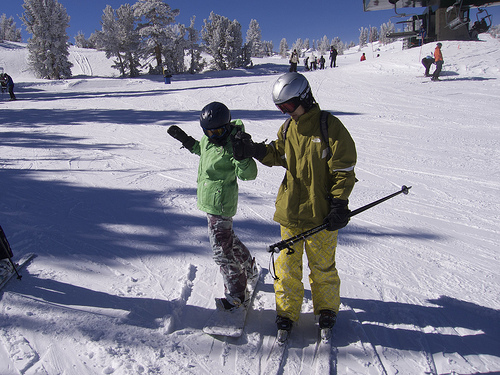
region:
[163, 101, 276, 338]
child balancing on top of a snow board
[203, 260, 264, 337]
snow board underneath child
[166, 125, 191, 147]
black mitten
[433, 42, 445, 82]
person wearing an orange jacket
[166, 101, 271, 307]
child weaqring a green jacket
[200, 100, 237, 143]
child wearing a black helmet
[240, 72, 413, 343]
person holding ski poles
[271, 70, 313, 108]
silver helmet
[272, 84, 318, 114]
ski goggles on top of helmet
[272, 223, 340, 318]
yellow ski pants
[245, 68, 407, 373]
a snow skier on slope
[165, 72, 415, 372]
a snow skier helping a snowboarder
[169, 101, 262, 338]
a snow boarder on slope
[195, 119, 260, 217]
a light green winter coat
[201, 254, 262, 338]
a snow covered snowboard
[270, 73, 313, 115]
a silver protective helmet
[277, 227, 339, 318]
a yellow pair of snow pants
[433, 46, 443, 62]
an orange winter coat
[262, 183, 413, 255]
a black snow pole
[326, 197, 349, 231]
a black winter snow glove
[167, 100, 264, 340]
boy standing on skateboard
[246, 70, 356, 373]
person wearing skis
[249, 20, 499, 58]
trees in the distance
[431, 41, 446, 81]
person standing on the snow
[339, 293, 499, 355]
peoples shadow on the snow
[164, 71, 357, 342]
two people wearing helmet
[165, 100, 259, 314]
person wearing green helmet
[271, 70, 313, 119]
grey helmet on head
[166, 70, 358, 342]
two people wearing gloves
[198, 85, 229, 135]
Person wearing black helmet.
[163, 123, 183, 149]
Person wearing black glove.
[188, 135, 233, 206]
Person wearing green jacket.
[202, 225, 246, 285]
Person wearing gray pants.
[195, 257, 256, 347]
Person standing on snowboard.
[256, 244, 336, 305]
Person wearing yellow pants.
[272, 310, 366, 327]
Person wearing black boots.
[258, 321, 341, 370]
Person standing on 2 skis.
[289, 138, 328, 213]
Person wearing olive green coat.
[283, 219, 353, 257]
Person holding ski poles.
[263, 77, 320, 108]
the helmet is silver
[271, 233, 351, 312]
the pants are yellow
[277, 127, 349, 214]
the jacket is brown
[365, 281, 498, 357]
shadow is on the ground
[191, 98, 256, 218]
the jacket is green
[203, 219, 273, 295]
the pants are camouflage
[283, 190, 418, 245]
pole is on the hand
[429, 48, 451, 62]
the shirt is orange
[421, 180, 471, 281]
skitracks are on the snow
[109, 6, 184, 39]
snow is on the tree